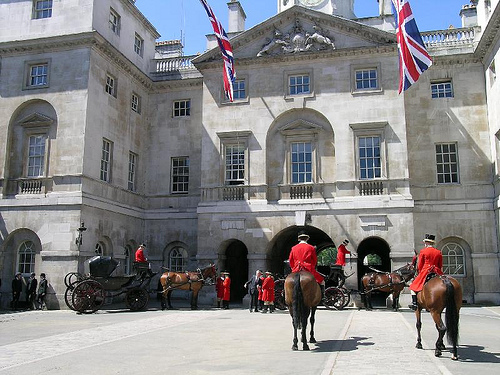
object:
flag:
[385, 1, 428, 96]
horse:
[157, 263, 218, 311]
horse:
[283, 271, 322, 350]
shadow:
[309, 336, 374, 353]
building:
[0, 0, 500, 312]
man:
[281, 231, 328, 301]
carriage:
[64, 255, 172, 314]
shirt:
[135, 248, 146, 262]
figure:
[256, 18, 336, 58]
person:
[258, 270, 274, 313]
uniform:
[409, 245, 444, 296]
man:
[133, 243, 158, 277]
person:
[35, 273, 47, 310]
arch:
[266, 225, 342, 269]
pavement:
[0, 305, 499, 375]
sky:
[132, 0, 476, 64]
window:
[170, 156, 189, 195]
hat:
[422, 234, 436, 245]